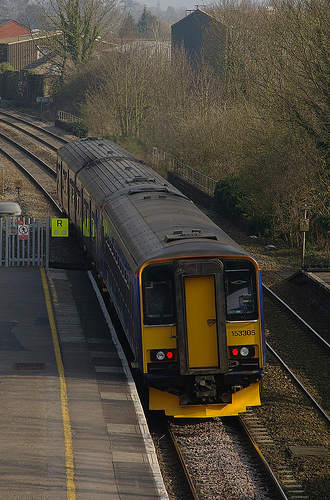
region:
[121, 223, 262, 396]
this is a train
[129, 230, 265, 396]
the train is moving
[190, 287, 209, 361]
the front is yellow in color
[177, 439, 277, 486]
these are the rails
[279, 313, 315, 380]
the rails are metallic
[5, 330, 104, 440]
this is a pavement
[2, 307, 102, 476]
the pavement is tarmacked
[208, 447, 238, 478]
small stones are in the middle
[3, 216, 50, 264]
this is the fence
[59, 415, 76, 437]
yellow strip is drawn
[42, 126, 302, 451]
train on the tracks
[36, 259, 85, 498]
yellow line on the ground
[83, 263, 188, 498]
white line on the ground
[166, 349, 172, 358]
small red light on the front of the train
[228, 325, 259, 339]
black numbers on a yellow background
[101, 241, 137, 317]
row of windows on the side of the train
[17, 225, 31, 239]
red, white, and black sign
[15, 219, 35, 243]
sign on the fence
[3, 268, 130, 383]
shadow on the ground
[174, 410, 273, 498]
gravel on the tracks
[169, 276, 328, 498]
two sets of train tracks running parallel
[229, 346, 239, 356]
small red light on the train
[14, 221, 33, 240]
sign hanging on the fence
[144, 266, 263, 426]
yellow paint on the front of the train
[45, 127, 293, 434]
a train on tracks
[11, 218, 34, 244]
a sign warning people to stay out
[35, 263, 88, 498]
a yellow caution line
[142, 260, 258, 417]
the front end of a train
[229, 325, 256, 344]
train indicated as 153305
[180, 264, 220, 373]
a yellow door on a train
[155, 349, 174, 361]
white and red indicator lights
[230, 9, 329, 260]
trees next to the train track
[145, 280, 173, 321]
a window on the train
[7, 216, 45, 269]
a fence used to keep people out of the area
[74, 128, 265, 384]
yellow and blue train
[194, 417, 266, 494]
light grey gravel between tracks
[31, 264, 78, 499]
yellow line on platform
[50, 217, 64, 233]
yellow and black sign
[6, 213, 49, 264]
grey fence behind yellow line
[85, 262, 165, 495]
white line next to train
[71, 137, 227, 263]
black roof on train cars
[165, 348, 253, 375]
red lights on train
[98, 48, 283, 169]
bare trees behind train tracks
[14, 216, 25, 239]
red and white sign